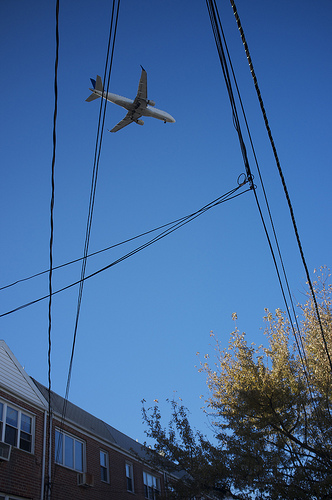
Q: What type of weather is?
A: It is clear.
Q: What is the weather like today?
A: It is clear.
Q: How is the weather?
A: It is clear.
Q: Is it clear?
A: Yes, it is clear.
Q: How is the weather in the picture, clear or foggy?
A: It is clear.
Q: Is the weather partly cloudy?
A: No, it is clear.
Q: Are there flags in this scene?
A: No, there are no flags.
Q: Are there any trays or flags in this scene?
A: No, there are no flags or trays.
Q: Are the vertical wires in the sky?
A: Yes, the wires are in the sky.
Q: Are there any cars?
A: No, there are no cars.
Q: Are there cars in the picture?
A: No, there are no cars.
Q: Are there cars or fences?
A: No, there are no cars or fences.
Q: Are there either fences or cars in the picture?
A: No, there are no cars or fences.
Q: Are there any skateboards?
A: No, there are no skateboards.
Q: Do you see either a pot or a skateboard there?
A: No, there are no skateboards or pots.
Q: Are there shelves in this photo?
A: No, there are no shelves.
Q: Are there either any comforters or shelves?
A: No, there are no shelves or comforters.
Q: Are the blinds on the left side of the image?
A: Yes, the blinds are on the left of the image.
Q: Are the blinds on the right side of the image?
A: No, the blinds are on the left of the image.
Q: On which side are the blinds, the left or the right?
A: The blinds are on the left of the image.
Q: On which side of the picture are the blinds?
A: The blinds are on the left of the image.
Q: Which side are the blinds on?
A: The blinds are on the left of the image.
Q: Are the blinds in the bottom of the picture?
A: Yes, the blinds are in the bottom of the image.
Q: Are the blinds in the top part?
A: No, the blinds are in the bottom of the image.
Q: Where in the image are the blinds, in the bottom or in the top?
A: The blinds are in the bottom of the image.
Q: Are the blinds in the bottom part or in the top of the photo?
A: The blinds are in the bottom of the image.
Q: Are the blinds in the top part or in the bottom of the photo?
A: The blinds are in the bottom of the image.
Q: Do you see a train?
A: No, there are no trains.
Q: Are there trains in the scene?
A: No, there are no trains.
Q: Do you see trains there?
A: No, there are no trains.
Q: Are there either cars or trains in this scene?
A: No, there are no trains or cars.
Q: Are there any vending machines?
A: No, there are no vending machines.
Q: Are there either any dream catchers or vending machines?
A: No, there are no vending machines or dream catchers.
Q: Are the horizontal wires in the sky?
A: Yes, the wires are in the sky.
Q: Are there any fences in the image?
A: No, there are no fences.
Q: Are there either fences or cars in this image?
A: No, there are no fences or cars.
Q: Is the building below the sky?
A: Yes, the building is below the sky.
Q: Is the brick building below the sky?
A: Yes, the building is below the sky.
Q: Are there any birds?
A: No, there are no birds.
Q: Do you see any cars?
A: No, there are no cars.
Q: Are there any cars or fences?
A: No, there are no cars or fences.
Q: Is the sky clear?
A: Yes, the sky is clear.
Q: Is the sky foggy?
A: No, the sky is clear.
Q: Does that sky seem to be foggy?
A: No, the sky is clear.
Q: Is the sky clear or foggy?
A: The sky is clear.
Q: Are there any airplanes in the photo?
A: Yes, there is an airplane.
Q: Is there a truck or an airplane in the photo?
A: Yes, there is an airplane.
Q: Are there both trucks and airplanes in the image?
A: No, there is an airplane but no trucks.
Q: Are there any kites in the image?
A: No, there are no kites.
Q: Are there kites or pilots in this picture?
A: No, there are no kites or pilots.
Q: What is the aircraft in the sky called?
A: The aircraft is an airplane.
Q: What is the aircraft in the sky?
A: The aircraft is an airplane.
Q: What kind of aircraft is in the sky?
A: The aircraft is an airplane.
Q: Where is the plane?
A: The plane is in the sky.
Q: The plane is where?
A: The plane is in the sky.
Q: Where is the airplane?
A: The plane is in the sky.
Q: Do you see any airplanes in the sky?
A: Yes, there is an airplane in the sky.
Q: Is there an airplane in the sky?
A: Yes, there is an airplane in the sky.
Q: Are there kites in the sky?
A: No, there is an airplane in the sky.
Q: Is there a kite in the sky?
A: No, there is an airplane in the sky.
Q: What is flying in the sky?
A: The plane is flying in the sky.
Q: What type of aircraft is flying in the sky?
A: The aircraft is an airplane.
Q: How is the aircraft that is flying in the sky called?
A: The aircraft is an airplane.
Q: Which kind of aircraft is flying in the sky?
A: The aircraft is an airplane.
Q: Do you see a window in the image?
A: Yes, there is a window.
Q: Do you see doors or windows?
A: Yes, there is a window.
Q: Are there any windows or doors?
A: Yes, there is a window.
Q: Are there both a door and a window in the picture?
A: No, there is a window but no doors.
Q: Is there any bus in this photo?
A: No, there are no buses.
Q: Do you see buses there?
A: No, there are no buses.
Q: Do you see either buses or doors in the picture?
A: No, there are no buses or doors.